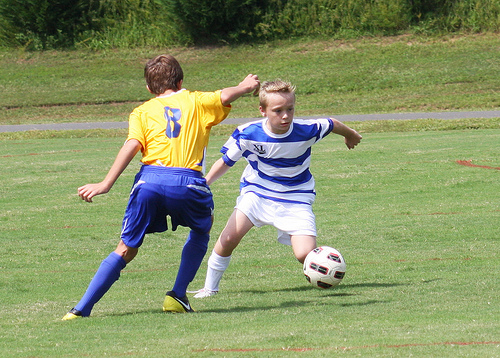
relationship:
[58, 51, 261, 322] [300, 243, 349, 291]
boy playing ball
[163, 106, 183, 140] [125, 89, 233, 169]
number on a yellow shirt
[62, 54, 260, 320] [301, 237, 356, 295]
boy tries to get a ball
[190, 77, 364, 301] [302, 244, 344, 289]
boy kicks a ball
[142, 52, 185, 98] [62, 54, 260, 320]
hair of  a boy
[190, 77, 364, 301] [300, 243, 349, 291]
boy playing ball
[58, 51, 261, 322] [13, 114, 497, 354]
boy in a field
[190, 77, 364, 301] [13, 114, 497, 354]
boy in a field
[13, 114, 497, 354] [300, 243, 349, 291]
field for playing ball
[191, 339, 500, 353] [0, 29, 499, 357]
red stripe on field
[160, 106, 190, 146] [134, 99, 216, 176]
number on jersey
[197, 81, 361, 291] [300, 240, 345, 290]
boy dribbling soccer ball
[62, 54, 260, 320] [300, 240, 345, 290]
boy dribbling soccer ball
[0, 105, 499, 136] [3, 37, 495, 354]
walkway bordering field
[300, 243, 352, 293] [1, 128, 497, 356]
ball on ground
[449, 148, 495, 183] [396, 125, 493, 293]
marking on grass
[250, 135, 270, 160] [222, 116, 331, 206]
size on shirt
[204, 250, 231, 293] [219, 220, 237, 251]
sock on knee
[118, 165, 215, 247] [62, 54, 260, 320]
shorts on boy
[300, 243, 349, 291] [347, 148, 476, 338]
ball on field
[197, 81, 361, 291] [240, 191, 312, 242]
boy in shorts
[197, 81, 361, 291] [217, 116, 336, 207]
boy in striped shirt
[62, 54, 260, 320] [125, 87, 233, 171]
boy in yellow shirt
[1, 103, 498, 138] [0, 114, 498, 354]
walkway past grass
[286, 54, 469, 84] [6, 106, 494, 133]
grass past path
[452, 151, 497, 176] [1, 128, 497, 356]
red stripe on ground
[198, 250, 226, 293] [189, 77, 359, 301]
sock on boy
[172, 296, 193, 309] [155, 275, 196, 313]
nike swoosh on right cleat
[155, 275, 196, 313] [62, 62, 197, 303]
right cleat on boy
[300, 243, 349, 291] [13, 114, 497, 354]
ball on field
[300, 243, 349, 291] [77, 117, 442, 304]
ball in air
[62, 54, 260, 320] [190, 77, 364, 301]
boy defending boy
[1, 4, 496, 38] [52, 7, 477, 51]
trees have bunch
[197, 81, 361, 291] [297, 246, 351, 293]
boy trying to get ball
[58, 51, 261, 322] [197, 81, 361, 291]
boy playing soccer against boy